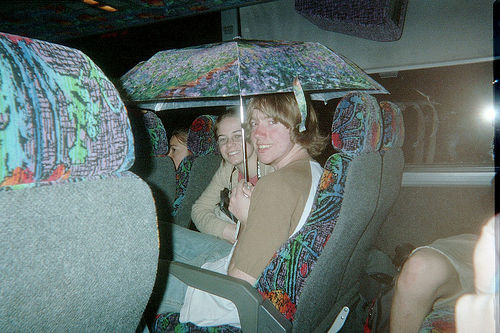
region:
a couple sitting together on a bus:
[160, 100, 324, 315]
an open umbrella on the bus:
[125, 35, 387, 177]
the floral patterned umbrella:
[118, 35, 385, 177]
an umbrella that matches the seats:
[117, 35, 389, 178]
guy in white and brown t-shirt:
[165, 97, 318, 322]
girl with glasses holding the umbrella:
[192, 111, 271, 239]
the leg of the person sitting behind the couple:
[388, 248, 457, 329]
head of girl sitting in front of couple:
[167, 132, 189, 167]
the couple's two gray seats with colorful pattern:
[172, 95, 402, 327]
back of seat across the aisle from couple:
[0, 35, 159, 327]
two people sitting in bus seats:
[169, 94, 386, 331]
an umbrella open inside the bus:
[107, 27, 385, 244]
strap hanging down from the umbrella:
[293, 77, 310, 137]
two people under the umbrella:
[126, 30, 355, 330]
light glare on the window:
[480, 100, 496, 128]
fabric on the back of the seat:
[1, 31, 131, 183]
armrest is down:
[166, 249, 258, 320]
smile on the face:
[253, 140, 273, 154]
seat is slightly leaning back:
[176, 112, 223, 218]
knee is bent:
[387, 231, 437, 330]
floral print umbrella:
[103, 25, 395, 117]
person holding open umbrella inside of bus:
[98, 20, 393, 330]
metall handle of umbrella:
[231, 100, 261, 200]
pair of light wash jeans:
[163, 218, 238, 323]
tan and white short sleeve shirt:
[183, 152, 330, 330]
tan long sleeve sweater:
[185, 147, 273, 248]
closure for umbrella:
[279, 70, 321, 137]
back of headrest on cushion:
[0, 23, 141, 206]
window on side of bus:
[370, 51, 496, 183]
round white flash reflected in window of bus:
[466, 93, 498, 136]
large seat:
[0, 30, 161, 329]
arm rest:
[166, 263, 291, 328]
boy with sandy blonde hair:
[244, 94, 326, 151]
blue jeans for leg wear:
[158, 228, 224, 260]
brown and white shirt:
[253, 180, 305, 227]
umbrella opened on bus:
[117, 42, 382, 97]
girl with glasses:
[215, 103, 242, 159]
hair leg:
[393, 251, 436, 331]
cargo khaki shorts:
[430, 226, 469, 288]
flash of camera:
[467, 80, 499, 119]